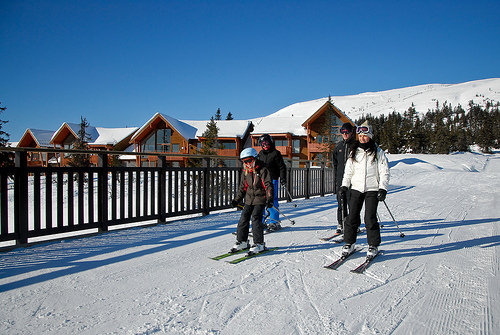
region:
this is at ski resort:
[33, 30, 459, 309]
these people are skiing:
[215, 144, 415, 262]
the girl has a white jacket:
[349, 141, 404, 186]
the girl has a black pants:
[334, 191, 410, 238]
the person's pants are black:
[231, 204, 287, 244]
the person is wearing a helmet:
[240, 154, 276, 171]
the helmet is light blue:
[231, 134, 266, 166]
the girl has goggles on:
[334, 102, 386, 149]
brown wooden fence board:
[31, 173, 44, 231]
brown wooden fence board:
[43, 171, 52, 231]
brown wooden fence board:
[66, 171, 74, 228]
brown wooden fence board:
[76, 171, 86, 226]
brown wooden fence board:
[86, 169, 96, 226]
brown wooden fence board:
[111, 173, 116, 222]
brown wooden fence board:
[119, 168, 126, 223]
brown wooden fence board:
[128, 170, 135, 217]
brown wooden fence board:
[150, 170, 157, 217]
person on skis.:
[325, 112, 407, 277]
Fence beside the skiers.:
[0, 140, 341, 250]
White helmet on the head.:
[230, 140, 260, 172]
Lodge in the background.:
[2, 100, 357, 170]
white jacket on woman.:
[325, 112, 391, 197]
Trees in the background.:
[350, 100, 495, 157]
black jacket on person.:
[252, 126, 289, 182]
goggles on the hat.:
[345, 116, 375, 146]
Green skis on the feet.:
[205, 236, 275, 267]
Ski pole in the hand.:
[369, 186, 410, 242]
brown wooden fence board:
[0, 173, 10, 235]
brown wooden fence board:
[15, 173, 27, 233]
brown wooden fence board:
[33, 172, 43, 231]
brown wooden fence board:
[56, 172, 66, 230]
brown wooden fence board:
[66, 173, 73, 227]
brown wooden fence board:
[78, 171, 85, 226]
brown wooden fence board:
[87, 172, 94, 222]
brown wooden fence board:
[97, 172, 106, 223]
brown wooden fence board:
[111, 173, 119, 221]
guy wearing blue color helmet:
[239, 148, 256, 160]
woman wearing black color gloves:
[377, 188, 385, 200]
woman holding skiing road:
[384, 201, 401, 238]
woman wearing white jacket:
[349, 152, 376, 189]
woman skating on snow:
[328, 247, 376, 274]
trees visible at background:
[393, 113, 479, 152]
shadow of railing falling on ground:
[62, 233, 155, 267]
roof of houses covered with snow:
[270, 105, 325, 129]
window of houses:
[214, 141, 234, 148]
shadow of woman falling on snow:
[383, 244, 494, 259]